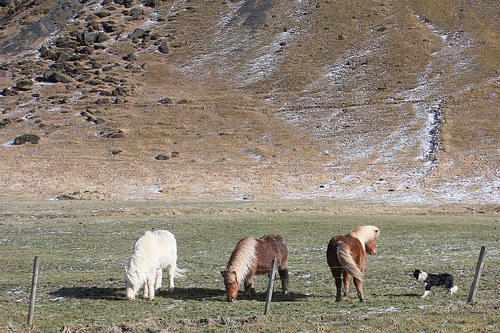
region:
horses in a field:
[15, 120, 490, 309]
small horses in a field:
[89, 116, 479, 328]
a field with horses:
[21, 146, 449, 331]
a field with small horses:
[23, 168, 430, 331]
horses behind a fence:
[55, 137, 420, 330]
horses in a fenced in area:
[59, 120, 496, 330]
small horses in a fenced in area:
[111, 156, 446, 330]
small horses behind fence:
[62, 147, 392, 329]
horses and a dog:
[94, 162, 490, 322]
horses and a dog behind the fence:
[99, 185, 496, 330]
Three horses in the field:
[86, 173, 378, 315]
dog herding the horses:
[406, 252, 468, 296]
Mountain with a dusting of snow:
[54, 50, 457, 167]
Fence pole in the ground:
[15, 240, 52, 319]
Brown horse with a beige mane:
[216, 215, 301, 301]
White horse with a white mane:
[71, 207, 191, 305]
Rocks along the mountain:
[36, 18, 152, 140]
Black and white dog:
[407, 262, 462, 299]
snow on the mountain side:
[303, 59, 458, 168]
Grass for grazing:
[10, 218, 97, 250]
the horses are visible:
[87, 157, 358, 320]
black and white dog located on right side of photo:
[403, 256, 460, 303]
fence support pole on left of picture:
[13, 251, 46, 327]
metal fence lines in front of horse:
[291, 252, 334, 300]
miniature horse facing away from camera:
[320, 226, 407, 298]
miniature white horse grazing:
[82, 207, 198, 323]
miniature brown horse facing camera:
[189, 203, 301, 330]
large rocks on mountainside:
[49, 19, 131, 102]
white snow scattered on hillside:
[321, 41, 356, 140]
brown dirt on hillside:
[201, 117, 285, 169]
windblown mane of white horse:
[116, 223, 174, 290]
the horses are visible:
[150, 210, 430, 327]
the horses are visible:
[66, 120, 431, 285]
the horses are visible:
[170, 230, 317, 313]